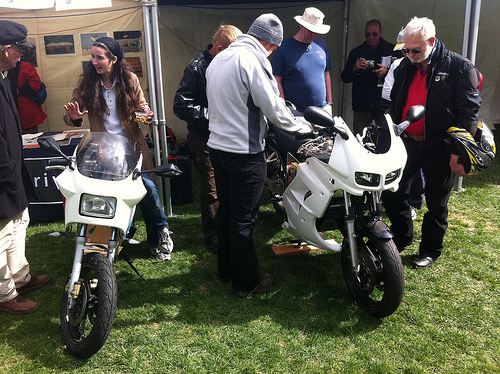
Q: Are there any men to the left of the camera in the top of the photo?
A: Yes, there is a man to the left of the camera.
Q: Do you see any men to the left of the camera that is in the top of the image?
A: Yes, there is a man to the left of the camera.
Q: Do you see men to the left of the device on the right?
A: Yes, there is a man to the left of the camera.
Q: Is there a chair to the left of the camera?
A: No, there is a man to the left of the camera.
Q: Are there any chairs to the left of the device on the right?
A: No, there is a man to the left of the camera.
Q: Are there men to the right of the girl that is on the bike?
A: Yes, there is a man to the right of the girl.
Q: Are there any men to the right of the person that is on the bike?
A: Yes, there is a man to the right of the girl.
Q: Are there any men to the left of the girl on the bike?
A: No, the man is to the right of the girl.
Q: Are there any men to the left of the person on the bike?
A: No, the man is to the right of the girl.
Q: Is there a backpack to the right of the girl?
A: No, there is a man to the right of the girl.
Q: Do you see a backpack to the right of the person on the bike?
A: No, there is a man to the right of the girl.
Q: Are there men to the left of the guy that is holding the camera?
A: Yes, there is a man to the left of the guy.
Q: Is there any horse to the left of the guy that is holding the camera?
A: No, there is a man to the left of the guy.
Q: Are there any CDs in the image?
A: No, there are no cds.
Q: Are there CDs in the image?
A: No, there are no cds.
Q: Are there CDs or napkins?
A: No, there are no CDs or napkins.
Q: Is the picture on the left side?
A: Yes, the picture is on the left of the image.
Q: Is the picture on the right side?
A: No, the picture is on the left of the image.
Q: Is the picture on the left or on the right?
A: The picture is on the left of the image.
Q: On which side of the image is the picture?
A: The picture is on the left of the image.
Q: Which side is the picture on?
A: The picture is on the left of the image.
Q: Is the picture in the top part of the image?
A: Yes, the picture is in the top of the image.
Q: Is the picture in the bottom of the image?
A: No, the picture is in the top of the image.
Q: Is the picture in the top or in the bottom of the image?
A: The picture is in the top of the image.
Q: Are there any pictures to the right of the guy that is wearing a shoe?
A: Yes, there is a picture to the right of the guy.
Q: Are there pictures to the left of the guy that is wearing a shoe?
A: No, the picture is to the right of the guy.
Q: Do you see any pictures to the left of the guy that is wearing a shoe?
A: No, the picture is to the right of the guy.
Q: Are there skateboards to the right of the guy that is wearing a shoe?
A: No, there is a picture to the right of the guy.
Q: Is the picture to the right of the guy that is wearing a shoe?
A: Yes, the picture is to the right of the guy.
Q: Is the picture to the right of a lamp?
A: No, the picture is to the right of the guy.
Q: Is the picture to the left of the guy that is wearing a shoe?
A: No, the picture is to the right of the guy.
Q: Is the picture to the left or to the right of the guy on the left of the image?
A: The picture is to the right of the guy.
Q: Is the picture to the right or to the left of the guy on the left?
A: The picture is to the right of the guy.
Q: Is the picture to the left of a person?
A: Yes, the picture is to the left of a person.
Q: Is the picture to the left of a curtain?
A: No, the picture is to the left of a person.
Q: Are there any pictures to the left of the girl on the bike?
A: Yes, there is a picture to the left of the girl.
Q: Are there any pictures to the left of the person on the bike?
A: Yes, there is a picture to the left of the girl.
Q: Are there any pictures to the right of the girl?
A: No, the picture is to the left of the girl.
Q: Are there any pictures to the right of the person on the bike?
A: No, the picture is to the left of the girl.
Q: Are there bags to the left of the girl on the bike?
A: No, there is a picture to the left of the girl.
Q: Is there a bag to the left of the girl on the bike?
A: No, there is a picture to the left of the girl.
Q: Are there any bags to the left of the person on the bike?
A: No, there is a picture to the left of the girl.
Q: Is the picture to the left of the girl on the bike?
A: Yes, the picture is to the left of the girl.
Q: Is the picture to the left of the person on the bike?
A: Yes, the picture is to the left of the girl.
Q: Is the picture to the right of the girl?
A: No, the picture is to the left of the girl.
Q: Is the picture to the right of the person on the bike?
A: No, the picture is to the left of the girl.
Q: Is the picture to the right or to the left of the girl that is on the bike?
A: The picture is to the left of the girl.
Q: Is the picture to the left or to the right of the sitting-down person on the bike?
A: The picture is to the left of the girl.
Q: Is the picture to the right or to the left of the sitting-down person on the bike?
A: The picture is to the left of the girl.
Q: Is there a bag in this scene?
A: No, there are no bags.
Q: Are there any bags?
A: No, there are no bags.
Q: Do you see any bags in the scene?
A: No, there are no bags.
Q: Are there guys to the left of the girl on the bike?
A: Yes, there is a guy to the left of the girl.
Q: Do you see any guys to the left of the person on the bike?
A: Yes, there is a guy to the left of the girl.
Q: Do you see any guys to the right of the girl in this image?
A: No, the guy is to the left of the girl.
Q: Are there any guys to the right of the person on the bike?
A: No, the guy is to the left of the girl.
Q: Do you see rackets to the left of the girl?
A: No, there is a guy to the left of the girl.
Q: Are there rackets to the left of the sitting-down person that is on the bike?
A: No, there is a guy to the left of the girl.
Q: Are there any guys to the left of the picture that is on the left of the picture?
A: Yes, there is a guy to the left of the picture.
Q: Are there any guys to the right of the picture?
A: No, the guy is to the left of the picture.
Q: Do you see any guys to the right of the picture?
A: No, the guy is to the left of the picture.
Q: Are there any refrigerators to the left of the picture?
A: No, there is a guy to the left of the picture.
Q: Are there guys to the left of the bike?
A: Yes, there is a guy to the left of the bike.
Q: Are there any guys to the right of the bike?
A: No, the guy is to the left of the bike.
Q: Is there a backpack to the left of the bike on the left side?
A: No, there is a guy to the left of the bike.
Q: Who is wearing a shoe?
A: The guy is wearing a shoe.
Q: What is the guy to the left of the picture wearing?
A: The guy is wearing a shoe.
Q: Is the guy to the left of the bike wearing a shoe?
A: Yes, the guy is wearing a shoe.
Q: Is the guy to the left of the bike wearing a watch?
A: No, the guy is wearing a shoe.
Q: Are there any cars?
A: No, there are no cars.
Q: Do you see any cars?
A: No, there are no cars.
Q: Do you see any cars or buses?
A: No, there are no cars or buses.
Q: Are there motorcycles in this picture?
A: Yes, there is a motorcycle.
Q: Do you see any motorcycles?
A: Yes, there is a motorcycle.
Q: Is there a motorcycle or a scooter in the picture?
A: Yes, there is a motorcycle.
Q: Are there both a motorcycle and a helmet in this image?
A: Yes, there are both a motorcycle and a helmet.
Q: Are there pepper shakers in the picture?
A: No, there are no pepper shakers.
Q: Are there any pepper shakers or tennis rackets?
A: No, there are no pepper shakers or tennis rackets.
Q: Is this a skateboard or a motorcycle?
A: This is a motorcycle.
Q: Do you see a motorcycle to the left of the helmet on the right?
A: Yes, there is a motorcycle to the left of the helmet.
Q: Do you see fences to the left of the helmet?
A: No, there is a motorcycle to the left of the helmet.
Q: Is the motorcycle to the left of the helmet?
A: Yes, the motorcycle is to the left of the helmet.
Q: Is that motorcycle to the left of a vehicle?
A: No, the motorcycle is to the left of the helmet.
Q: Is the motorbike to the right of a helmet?
A: No, the motorbike is to the left of a helmet.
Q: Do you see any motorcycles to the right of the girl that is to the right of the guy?
A: Yes, there is a motorcycle to the right of the girl.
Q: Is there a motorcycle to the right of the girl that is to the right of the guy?
A: Yes, there is a motorcycle to the right of the girl.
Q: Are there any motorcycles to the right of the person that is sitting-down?
A: Yes, there is a motorcycle to the right of the girl.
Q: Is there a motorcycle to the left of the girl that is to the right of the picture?
A: No, the motorcycle is to the right of the girl.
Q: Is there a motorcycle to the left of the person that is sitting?
A: No, the motorcycle is to the right of the girl.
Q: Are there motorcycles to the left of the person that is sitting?
A: No, the motorcycle is to the right of the girl.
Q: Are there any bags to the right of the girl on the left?
A: No, there is a motorcycle to the right of the girl.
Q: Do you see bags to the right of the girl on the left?
A: No, there is a motorcycle to the right of the girl.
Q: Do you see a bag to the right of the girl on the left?
A: No, there is a motorcycle to the right of the girl.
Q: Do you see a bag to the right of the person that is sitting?
A: No, there is a motorcycle to the right of the girl.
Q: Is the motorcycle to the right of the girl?
A: Yes, the motorcycle is to the right of the girl.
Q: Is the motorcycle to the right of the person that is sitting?
A: Yes, the motorcycle is to the right of the girl.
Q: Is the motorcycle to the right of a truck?
A: No, the motorcycle is to the right of the girl.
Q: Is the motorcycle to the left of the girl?
A: No, the motorcycle is to the right of the girl.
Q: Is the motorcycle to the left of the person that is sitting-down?
A: No, the motorcycle is to the right of the girl.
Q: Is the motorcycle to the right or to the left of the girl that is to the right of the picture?
A: The motorcycle is to the right of the girl.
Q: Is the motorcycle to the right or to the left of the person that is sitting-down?
A: The motorcycle is to the right of the girl.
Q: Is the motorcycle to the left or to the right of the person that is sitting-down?
A: The motorcycle is to the right of the girl.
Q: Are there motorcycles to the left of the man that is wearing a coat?
A: Yes, there is a motorcycle to the left of the man.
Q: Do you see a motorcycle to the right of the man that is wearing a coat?
A: No, the motorcycle is to the left of the man.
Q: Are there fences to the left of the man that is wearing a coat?
A: No, there is a motorcycle to the left of the man.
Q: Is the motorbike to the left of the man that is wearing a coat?
A: Yes, the motorbike is to the left of the man.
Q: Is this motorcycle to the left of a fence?
A: No, the motorcycle is to the left of the man.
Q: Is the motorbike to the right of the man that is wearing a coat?
A: No, the motorbike is to the left of the man.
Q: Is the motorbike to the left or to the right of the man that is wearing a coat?
A: The motorbike is to the left of the man.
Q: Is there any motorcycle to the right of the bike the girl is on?
A: Yes, there is a motorcycle to the right of the bike.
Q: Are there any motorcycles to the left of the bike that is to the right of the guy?
A: No, the motorcycle is to the right of the bike.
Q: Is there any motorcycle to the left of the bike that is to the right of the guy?
A: No, the motorcycle is to the right of the bike.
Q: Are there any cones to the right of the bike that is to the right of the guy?
A: No, there is a motorcycle to the right of the bike.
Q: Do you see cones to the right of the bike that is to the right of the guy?
A: No, there is a motorcycle to the right of the bike.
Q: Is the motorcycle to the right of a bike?
A: Yes, the motorcycle is to the right of a bike.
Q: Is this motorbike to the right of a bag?
A: No, the motorbike is to the right of a bike.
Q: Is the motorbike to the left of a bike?
A: No, the motorbike is to the right of a bike.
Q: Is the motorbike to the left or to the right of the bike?
A: The motorbike is to the right of the bike.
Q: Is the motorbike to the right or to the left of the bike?
A: The motorbike is to the right of the bike.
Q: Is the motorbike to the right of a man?
A: Yes, the motorbike is to the right of a man.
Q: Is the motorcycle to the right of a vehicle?
A: No, the motorcycle is to the right of a man.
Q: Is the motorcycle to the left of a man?
A: No, the motorcycle is to the right of a man.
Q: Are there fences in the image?
A: No, there are no fences.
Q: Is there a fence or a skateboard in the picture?
A: No, there are no fences or skateboards.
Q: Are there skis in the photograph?
A: No, there are no skis.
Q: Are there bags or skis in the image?
A: No, there are no skis or bags.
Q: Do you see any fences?
A: No, there are no fences.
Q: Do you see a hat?
A: Yes, there is a hat.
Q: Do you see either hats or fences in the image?
A: Yes, there is a hat.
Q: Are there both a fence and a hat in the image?
A: No, there is a hat but no fences.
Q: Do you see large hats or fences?
A: Yes, there is a large hat.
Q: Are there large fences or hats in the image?
A: Yes, there is a large hat.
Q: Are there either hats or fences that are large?
A: Yes, the hat is large.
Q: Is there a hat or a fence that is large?
A: Yes, the hat is large.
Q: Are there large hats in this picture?
A: Yes, there is a large hat.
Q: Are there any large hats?
A: Yes, there is a large hat.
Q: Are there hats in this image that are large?
A: Yes, there is a large hat.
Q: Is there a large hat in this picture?
A: Yes, there is a large hat.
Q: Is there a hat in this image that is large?
A: Yes, there is a hat that is large.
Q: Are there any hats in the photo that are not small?
A: Yes, there is a large hat.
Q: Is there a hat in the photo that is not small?
A: Yes, there is a large hat.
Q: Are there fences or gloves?
A: No, there are no fences or gloves.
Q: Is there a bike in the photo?
A: Yes, there is a bike.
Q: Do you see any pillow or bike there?
A: Yes, there is a bike.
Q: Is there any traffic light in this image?
A: No, there are no traffic lights.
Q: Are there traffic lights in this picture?
A: No, there are no traffic lights.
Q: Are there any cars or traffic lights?
A: No, there are no traffic lights or cars.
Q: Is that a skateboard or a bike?
A: That is a bike.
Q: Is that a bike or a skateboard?
A: That is a bike.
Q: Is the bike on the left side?
A: Yes, the bike is on the left of the image.